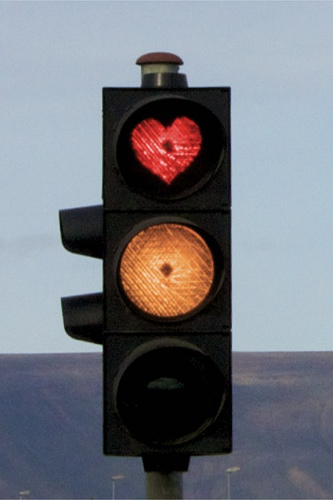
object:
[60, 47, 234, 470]
light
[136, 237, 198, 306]
color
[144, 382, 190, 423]
color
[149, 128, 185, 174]
color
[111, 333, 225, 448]
light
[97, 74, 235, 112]
top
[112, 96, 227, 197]
circle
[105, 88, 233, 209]
light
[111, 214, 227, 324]
circle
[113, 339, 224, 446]
circle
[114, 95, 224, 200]
light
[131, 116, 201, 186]
heart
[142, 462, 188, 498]
post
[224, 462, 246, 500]
light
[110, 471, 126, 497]
light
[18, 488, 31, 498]
light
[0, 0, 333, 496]
background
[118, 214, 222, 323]
light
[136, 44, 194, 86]
top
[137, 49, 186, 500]
post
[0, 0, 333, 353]
sky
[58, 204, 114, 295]
lights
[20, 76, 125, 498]
left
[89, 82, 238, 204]
light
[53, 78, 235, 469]
light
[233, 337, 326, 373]
skyline